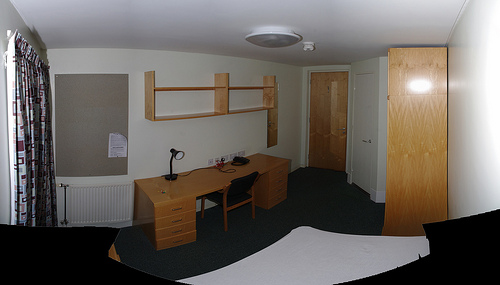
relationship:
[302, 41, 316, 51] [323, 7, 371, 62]
fire alarm on ceiling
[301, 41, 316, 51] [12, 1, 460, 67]
fire alarm on ceiling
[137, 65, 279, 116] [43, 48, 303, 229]
book shelf on wall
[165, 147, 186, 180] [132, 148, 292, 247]
lamp on desk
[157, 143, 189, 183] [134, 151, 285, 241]
lamp on desk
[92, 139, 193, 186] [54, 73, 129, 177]
paper on cork board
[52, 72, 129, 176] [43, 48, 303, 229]
cork board on wall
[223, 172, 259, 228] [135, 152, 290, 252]
chair in front of desk